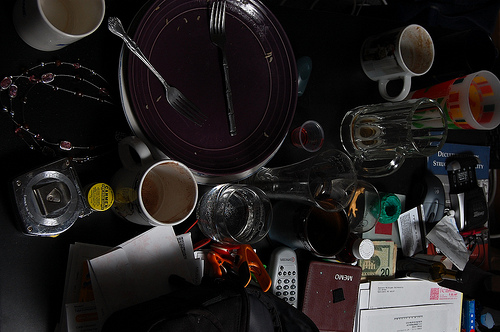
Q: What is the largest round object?
A: Plate.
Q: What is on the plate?
A: Forks.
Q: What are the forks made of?
A: Metal.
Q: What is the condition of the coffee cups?
A: Dirty.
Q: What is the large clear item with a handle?
A: Mug.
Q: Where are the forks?
A: On the plate.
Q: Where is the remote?
A: Bottom middle of the image.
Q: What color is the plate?
A: Purple.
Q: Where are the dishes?
A: On the counter.